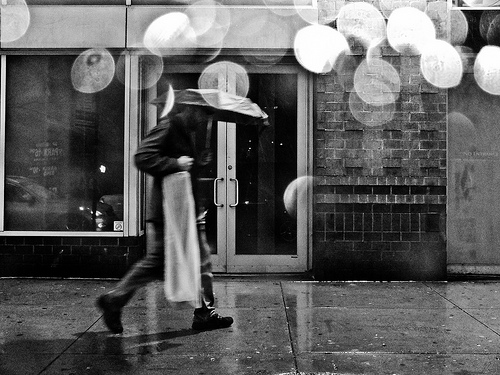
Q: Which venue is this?
A: This is a sidewalk.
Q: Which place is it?
A: It is a sidewalk.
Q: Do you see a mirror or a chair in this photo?
A: No, there are no mirrors or chairs.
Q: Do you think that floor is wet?
A: Yes, the floor is wet.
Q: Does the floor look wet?
A: Yes, the floor is wet.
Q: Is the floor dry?
A: No, the floor is wet.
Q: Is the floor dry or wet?
A: The floor is wet.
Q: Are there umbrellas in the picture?
A: Yes, there is an umbrella.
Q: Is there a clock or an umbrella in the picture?
A: Yes, there is an umbrella.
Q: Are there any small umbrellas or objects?
A: Yes, there is a small umbrella.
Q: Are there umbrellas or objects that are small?
A: Yes, the umbrella is small.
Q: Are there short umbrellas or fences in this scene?
A: Yes, there is a short umbrella.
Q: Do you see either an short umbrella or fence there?
A: Yes, there is a short umbrella.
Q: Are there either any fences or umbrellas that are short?
A: Yes, the umbrella is short.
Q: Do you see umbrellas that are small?
A: Yes, there is a small umbrella.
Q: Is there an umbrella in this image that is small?
A: Yes, there is an umbrella that is small.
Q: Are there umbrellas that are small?
A: Yes, there is an umbrella that is small.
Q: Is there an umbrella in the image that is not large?
A: Yes, there is a small umbrella.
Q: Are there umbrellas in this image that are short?
A: Yes, there is a short umbrella.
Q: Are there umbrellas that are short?
A: Yes, there is an umbrella that is short.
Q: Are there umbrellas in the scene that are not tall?
A: Yes, there is a short umbrella.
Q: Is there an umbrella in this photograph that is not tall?
A: Yes, there is a short umbrella.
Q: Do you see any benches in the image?
A: No, there are no benches.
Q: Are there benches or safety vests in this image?
A: No, there are no benches or safety vests.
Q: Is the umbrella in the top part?
A: Yes, the umbrella is in the top of the image.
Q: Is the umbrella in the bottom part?
A: No, the umbrella is in the top of the image.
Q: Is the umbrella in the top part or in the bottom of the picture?
A: The umbrella is in the top of the image.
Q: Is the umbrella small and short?
A: Yes, the umbrella is small and short.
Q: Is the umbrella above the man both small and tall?
A: No, the umbrella is small but short.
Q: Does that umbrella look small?
A: Yes, the umbrella is small.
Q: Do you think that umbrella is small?
A: Yes, the umbrella is small.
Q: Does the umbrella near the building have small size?
A: Yes, the umbrella is small.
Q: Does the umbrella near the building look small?
A: Yes, the umbrella is small.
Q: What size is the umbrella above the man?
A: The umbrella is small.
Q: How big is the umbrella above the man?
A: The umbrella is small.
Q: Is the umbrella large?
A: No, the umbrella is small.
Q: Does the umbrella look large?
A: No, the umbrella is small.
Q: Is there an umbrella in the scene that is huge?
A: No, there is an umbrella but it is small.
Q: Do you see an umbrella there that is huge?
A: No, there is an umbrella but it is small.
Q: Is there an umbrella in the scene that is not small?
A: No, there is an umbrella but it is small.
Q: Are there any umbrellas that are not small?
A: No, there is an umbrella but it is small.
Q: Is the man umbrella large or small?
A: The umbrella is small.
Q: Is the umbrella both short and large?
A: No, the umbrella is short but small.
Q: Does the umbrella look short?
A: Yes, the umbrella is short.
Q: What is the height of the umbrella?
A: The umbrella is short.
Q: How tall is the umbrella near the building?
A: The umbrella is short.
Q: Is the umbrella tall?
A: No, the umbrella is short.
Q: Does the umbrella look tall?
A: No, the umbrella is short.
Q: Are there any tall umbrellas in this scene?
A: No, there is an umbrella but it is short.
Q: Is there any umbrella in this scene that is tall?
A: No, there is an umbrella but it is short.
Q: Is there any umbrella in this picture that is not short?
A: No, there is an umbrella but it is short.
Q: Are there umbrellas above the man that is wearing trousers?
A: Yes, there is an umbrella above the man.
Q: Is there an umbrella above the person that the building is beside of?
A: Yes, there is an umbrella above the man.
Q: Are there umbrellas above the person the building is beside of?
A: Yes, there is an umbrella above the man.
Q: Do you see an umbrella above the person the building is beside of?
A: Yes, there is an umbrella above the man.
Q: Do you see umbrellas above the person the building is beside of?
A: Yes, there is an umbrella above the man.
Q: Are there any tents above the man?
A: No, there is an umbrella above the man.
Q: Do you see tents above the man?
A: No, there is an umbrella above the man.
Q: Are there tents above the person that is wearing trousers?
A: No, there is an umbrella above the man.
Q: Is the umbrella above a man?
A: Yes, the umbrella is above a man.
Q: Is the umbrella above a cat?
A: No, the umbrella is above a man.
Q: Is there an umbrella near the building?
A: Yes, there is an umbrella near the building.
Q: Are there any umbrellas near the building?
A: Yes, there is an umbrella near the building.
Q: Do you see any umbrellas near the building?
A: Yes, there is an umbrella near the building.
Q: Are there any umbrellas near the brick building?
A: Yes, there is an umbrella near the building.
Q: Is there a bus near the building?
A: No, there is an umbrella near the building.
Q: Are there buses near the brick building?
A: No, there is an umbrella near the building.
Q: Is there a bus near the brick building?
A: No, there is an umbrella near the building.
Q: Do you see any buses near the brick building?
A: No, there is an umbrella near the building.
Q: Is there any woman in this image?
A: No, there are no women.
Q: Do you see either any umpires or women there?
A: No, there are no women or umpires.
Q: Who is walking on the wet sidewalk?
A: The man is walking on the sidewalk.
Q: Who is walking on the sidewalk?
A: The man is walking on the sidewalk.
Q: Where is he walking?
A: The man is walking on the sidewalk.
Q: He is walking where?
A: The man is walking on the sidewalk.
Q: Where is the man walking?
A: The man is walking on the sidewalk.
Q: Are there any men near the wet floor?
A: Yes, there is a man near the floor.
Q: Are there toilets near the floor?
A: No, there is a man near the floor.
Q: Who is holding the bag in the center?
A: The man is holding the bag.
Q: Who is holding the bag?
A: The man is holding the bag.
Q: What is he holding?
A: The man is holding the bag.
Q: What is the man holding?
A: The man is holding the bag.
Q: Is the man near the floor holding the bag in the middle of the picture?
A: Yes, the man is holding the bag.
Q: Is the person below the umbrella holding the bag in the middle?
A: Yes, the man is holding the bag.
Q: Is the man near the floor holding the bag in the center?
A: Yes, the man is holding the bag.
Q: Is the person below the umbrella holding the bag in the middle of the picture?
A: Yes, the man is holding the bag.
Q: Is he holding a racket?
A: No, the man is holding the bag.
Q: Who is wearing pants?
A: The man is wearing pants.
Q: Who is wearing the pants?
A: The man is wearing pants.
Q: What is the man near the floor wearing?
A: The man is wearing trousers.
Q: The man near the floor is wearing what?
A: The man is wearing trousers.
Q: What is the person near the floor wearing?
A: The man is wearing trousers.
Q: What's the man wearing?
A: The man is wearing trousers.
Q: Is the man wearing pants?
A: Yes, the man is wearing pants.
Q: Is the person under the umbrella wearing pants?
A: Yes, the man is wearing pants.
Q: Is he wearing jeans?
A: No, the man is wearing pants.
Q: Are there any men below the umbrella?
A: Yes, there is a man below the umbrella.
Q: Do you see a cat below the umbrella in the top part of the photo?
A: No, there is a man below the umbrella.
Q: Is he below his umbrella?
A: Yes, the man is below the umbrella.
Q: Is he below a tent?
A: No, the man is below the umbrella.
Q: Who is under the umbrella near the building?
A: The man is under the umbrella.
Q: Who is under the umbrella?
A: The man is under the umbrella.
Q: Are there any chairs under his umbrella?
A: No, there is a man under the umbrella.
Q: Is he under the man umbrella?
A: Yes, the man is under the umbrella.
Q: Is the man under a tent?
A: No, the man is under the umbrella.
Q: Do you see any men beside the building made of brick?
A: Yes, there is a man beside the building.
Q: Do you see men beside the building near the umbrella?
A: Yes, there is a man beside the building.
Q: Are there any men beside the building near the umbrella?
A: Yes, there is a man beside the building.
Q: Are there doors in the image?
A: Yes, there are doors.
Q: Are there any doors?
A: Yes, there are doors.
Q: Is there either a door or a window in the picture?
A: Yes, there are doors.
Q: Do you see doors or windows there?
A: Yes, there are doors.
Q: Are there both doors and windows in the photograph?
A: Yes, there are both doors and a window.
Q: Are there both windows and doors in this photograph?
A: Yes, there are both doors and a window.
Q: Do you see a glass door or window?
A: Yes, there are glass doors.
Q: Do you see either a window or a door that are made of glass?
A: Yes, the doors are made of glass.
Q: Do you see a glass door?
A: Yes, there are doors that are made of glass.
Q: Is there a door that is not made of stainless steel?
A: Yes, there are doors that are made of glass.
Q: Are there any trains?
A: No, there are no trains.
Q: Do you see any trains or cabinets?
A: No, there are no trains or cabinets.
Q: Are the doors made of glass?
A: Yes, the doors are made of glass.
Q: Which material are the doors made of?
A: The doors are made of glass.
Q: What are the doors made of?
A: The doors are made of glass.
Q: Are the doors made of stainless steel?
A: No, the doors are made of glass.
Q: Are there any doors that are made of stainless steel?
A: No, there are doors but they are made of glass.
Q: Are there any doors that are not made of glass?
A: No, there are doors but they are made of glass.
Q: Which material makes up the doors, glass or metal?
A: The doors are made of glass.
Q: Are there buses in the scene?
A: No, there are no buses.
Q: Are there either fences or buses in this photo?
A: No, there are no buses or fences.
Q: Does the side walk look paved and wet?
A: Yes, the side walk is paved and wet.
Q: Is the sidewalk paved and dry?
A: No, the sidewalk is paved but wet.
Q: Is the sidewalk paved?
A: Yes, the sidewalk is paved.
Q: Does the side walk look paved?
A: Yes, the side walk is paved.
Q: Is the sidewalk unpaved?
A: No, the sidewalk is paved.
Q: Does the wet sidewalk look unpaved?
A: No, the sidewalk is paved.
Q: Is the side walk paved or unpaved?
A: The side walk is paved.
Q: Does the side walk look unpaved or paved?
A: The side walk is paved.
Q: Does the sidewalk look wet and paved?
A: Yes, the sidewalk is wet and paved.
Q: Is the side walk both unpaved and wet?
A: No, the side walk is wet but paved.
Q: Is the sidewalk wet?
A: Yes, the sidewalk is wet.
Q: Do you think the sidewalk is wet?
A: Yes, the sidewalk is wet.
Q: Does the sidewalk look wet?
A: Yes, the sidewalk is wet.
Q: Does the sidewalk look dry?
A: No, the sidewalk is wet.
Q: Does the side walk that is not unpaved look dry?
A: No, the side walk is wet.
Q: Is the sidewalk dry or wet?
A: The sidewalk is wet.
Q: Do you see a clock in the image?
A: No, there are no clocks.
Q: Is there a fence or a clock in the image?
A: No, there are no clocks or fences.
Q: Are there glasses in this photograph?
A: No, there are no glasses.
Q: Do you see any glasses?
A: No, there are no glasses.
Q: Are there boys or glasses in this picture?
A: No, there are no glasses or boys.